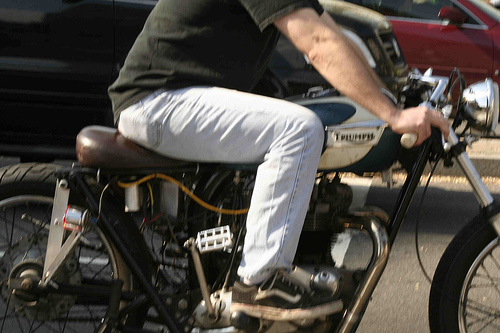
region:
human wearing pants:
[115, 73, 299, 280]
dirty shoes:
[234, 273, 335, 318]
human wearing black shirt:
[119, 3, 270, 93]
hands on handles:
[282, 5, 437, 147]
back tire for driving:
[0, 162, 165, 319]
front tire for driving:
[420, 185, 499, 331]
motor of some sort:
[278, 75, 396, 163]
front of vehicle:
[323, 3, 404, 86]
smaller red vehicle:
[378, 5, 490, 75]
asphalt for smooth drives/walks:
[391, 252, 412, 325]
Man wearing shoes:
[224, 275, 353, 322]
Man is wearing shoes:
[223, 274, 347, 324]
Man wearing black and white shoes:
[225, 270, 347, 325]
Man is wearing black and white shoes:
[227, 270, 347, 320]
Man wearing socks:
[237, 266, 283, 288]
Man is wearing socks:
[232, 265, 277, 285]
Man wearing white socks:
[235, 263, 274, 290]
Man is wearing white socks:
[233, 268, 279, 285]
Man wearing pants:
[115, 80, 328, 278]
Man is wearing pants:
[110, 79, 322, 275]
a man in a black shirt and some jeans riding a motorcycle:
[41, 2, 496, 326]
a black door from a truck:
[13, 8, 113, 108]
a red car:
[416, 0, 488, 69]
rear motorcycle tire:
[0, 151, 146, 331]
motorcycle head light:
[456, 74, 499, 138]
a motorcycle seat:
[74, 121, 188, 175]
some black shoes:
[218, 259, 339, 324]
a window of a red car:
[366, 1, 488, 29]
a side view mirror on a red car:
[432, 5, 469, 30]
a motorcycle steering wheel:
[389, 65, 476, 147]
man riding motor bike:
[108, 1, 449, 286]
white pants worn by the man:
[118, 87, 323, 286]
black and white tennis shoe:
[233, 276, 343, 320]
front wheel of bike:
[427, 197, 498, 331]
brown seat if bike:
[76, 125, 141, 167]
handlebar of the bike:
[398, 70, 448, 147]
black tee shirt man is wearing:
[107, 1, 324, 124]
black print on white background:
[330, 128, 377, 145]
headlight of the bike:
[463, 77, 494, 127]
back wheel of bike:
[0, 162, 155, 332]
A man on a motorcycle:
[122, 9, 351, 326]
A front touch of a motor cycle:
[457, 76, 498, 128]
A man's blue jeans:
[140, 91, 353, 291]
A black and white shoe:
[215, 248, 335, 323]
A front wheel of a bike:
[435, 214, 499, 329]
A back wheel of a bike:
[4, 159, 121, 329]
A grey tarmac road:
[380, 277, 421, 328]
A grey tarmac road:
[426, 175, 462, 230]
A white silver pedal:
[180, 226, 240, 306]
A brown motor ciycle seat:
[81, 121, 151, 162]